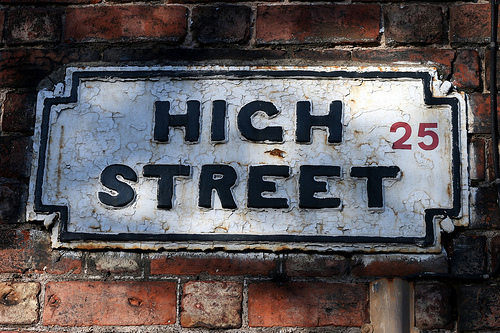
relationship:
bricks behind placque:
[0, 1, 497, 329] [19, 57, 474, 263]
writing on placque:
[95, 86, 447, 231] [19, 57, 474, 263]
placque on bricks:
[19, 57, 474, 263] [0, 1, 497, 329]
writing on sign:
[95, 86, 447, 231] [20, 62, 492, 250]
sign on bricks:
[20, 62, 492, 250] [0, 1, 497, 329]